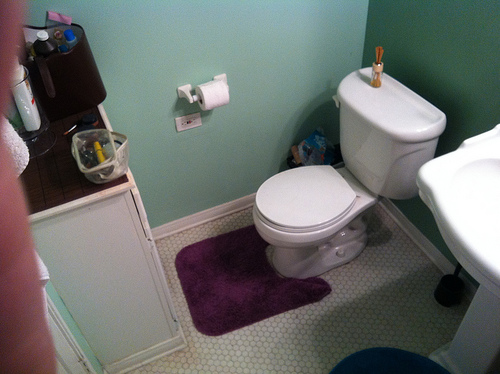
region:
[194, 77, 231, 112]
ROLL OF WHITE TOILET PAPER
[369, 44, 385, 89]
BROWN AROMA STICKS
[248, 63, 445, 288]
WHITE TOILET WITH THE LID DOWN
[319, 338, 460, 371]
BLUE AREA RUG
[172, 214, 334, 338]
PURPLE TOILET RUG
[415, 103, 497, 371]
WHITE PEDESTAL SINK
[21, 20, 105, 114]
CONTAINER WITH BEAUTY SUPPLIES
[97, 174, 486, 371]
WHITE TILED FLOOR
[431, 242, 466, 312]
BLACK TOILET BRUSH IN HOLDER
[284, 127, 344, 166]
MAGAZINE RACK NEXT TO THE TOILET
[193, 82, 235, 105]
a white colour napkin roll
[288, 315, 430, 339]
a cream colour tiles in the toilet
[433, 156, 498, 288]
white colour wash basin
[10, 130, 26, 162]
turkey towel in the hanger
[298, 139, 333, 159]
dust in the dustpin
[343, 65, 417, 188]
white colour flush tank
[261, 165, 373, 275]
white colour toilet sink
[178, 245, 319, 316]
brown colour mat on the toilet room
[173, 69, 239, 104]
white colour paper roll hanger in the wall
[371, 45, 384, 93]
brown colour brush in the top of the flush tank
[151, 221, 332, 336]
purple bathroom mat in front of toilet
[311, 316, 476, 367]
blue bathroom mat on floor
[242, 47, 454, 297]
white ceramic toilet in bathroom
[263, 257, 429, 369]
dirty white tile floor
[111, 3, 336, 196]
mint green colored wall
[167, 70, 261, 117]
toilet paper dispenser with roll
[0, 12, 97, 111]
assorted bathroom toiletries on cabinet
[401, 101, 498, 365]
white ceramic pedestal sink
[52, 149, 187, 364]
white bathroom cabinet on left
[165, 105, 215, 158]
power outlet under toilet paper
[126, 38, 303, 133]
Toilet paper dispenser on the wall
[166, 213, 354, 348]
Purplish rug around the toilet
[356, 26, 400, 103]
Fragrance dispenser on the toilet tank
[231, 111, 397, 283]
Toilet seat is closed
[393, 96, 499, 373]
Porcelain sink with no cabinet below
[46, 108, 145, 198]
Bag with cosmetics on the counter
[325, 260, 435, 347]
Small tiles on the floor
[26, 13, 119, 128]
Bottles of stuff on the counter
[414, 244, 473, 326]
Toilet brush on the floor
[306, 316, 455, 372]
Blue rug by the sink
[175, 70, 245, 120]
toilet paper holder on wall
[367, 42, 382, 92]
diffuser on the back of toilet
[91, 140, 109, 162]
mascara in makeup bag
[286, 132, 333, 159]
garbage on side of toilet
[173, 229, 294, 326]
purple mat on floor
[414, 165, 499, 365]
white pedestal sink in bathroom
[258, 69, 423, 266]
white toilet in bathroom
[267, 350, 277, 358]
small honeycomb tile on floor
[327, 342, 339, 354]
small honeycomb tile on floor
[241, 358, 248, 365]
small honeycomb tile on floor